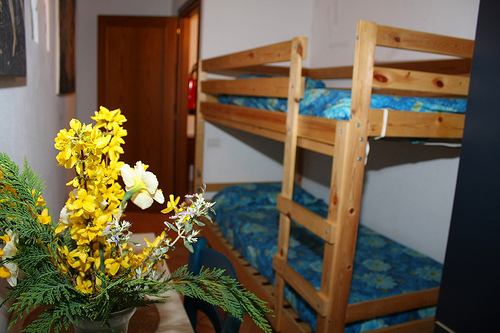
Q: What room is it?
A: It is a bedroom.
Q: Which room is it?
A: It is a bedroom.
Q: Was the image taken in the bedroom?
A: Yes, it was taken in the bedroom.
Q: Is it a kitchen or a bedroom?
A: It is a bedroom.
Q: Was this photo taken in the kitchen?
A: No, the picture was taken in the bedroom.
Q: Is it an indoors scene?
A: Yes, it is indoors.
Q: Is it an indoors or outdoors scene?
A: It is indoors.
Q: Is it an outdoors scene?
A: No, it is indoors.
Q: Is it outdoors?
A: No, it is indoors.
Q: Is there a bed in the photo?
A: Yes, there is a bed.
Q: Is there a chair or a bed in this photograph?
A: Yes, there is a bed.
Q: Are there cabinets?
A: No, there are no cabinets.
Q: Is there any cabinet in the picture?
A: No, there are no cabinets.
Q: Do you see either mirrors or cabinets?
A: No, there are no cabinets or mirrors.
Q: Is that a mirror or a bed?
A: That is a bed.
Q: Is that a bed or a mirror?
A: That is a bed.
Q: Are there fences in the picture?
A: No, there are no fences.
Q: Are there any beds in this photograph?
A: Yes, there is a bed.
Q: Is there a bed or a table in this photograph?
A: Yes, there is a bed.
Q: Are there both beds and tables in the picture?
A: Yes, there are both a bed and a table.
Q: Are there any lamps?
A: No, there are no lamps.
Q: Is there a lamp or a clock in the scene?
A: No, there are no lamps or clocks.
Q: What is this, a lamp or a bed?
A: This is a bed.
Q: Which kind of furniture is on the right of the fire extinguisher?
A: The piece of furniture is a bed.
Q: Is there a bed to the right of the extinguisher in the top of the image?
A: Yes, there is a bed to the right of the fire extinguisher.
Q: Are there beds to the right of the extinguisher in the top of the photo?
A: Yes, there is a bed to the right of the fire extinguisher.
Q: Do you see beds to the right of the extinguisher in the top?
A: Yes, there is a bed to the right of the fire extinguisher.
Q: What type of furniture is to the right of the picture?
A: The piece of furniture is a bed.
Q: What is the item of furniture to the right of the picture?
A: The piece of furniture is a bed.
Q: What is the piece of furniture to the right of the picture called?
A: The piece of furniture is a bed.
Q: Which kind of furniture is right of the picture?
A: The piece of furniture is a bed.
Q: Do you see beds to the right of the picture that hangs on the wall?
A: Yes, there is a bed to the right of the picture.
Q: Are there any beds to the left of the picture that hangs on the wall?
A: No, the bed is to the right of the picture.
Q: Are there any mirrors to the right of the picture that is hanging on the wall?
A: No, there is a bed to the right of the picture.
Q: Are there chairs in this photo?
A: Yes, there is a chair.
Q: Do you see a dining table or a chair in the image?
A: Yes, there is a chair.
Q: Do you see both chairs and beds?
A: Yes, there are both a chair and a bed.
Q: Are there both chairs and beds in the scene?
A: Yes, there are both a chair and a bed.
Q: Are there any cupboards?
A: No, there are no cupboards.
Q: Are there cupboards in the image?
A: No, there are no cupboards.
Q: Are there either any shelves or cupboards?
A: No, there are no cupboards or shelves.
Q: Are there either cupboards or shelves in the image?
A: No, there are no cupboards or shelves.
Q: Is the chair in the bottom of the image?
A: Yes, the chair is in the bottom of the image.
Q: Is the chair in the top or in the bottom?
A: The chair is in the bottom of the image.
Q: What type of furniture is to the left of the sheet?
A: The piece of furniture is a chair.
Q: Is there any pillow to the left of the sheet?
A: No, there is a chair to the left of the sheet.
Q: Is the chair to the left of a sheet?
A: Yes, the chair is to the left of a sheet.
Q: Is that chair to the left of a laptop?
A: No, the chair is to the left of a sheet.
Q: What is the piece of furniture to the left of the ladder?
A: The piece of furniture is a chair.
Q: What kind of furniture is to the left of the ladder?
A: The piece of furniture is a chair.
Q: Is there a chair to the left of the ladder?
A: Yes, there is a chair to the left of the ladder.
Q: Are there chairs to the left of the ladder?
A: Yes, there is a chair to the left of the ladder.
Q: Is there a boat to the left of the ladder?
A: No, there is a chair to the left of the ladder.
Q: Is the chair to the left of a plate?
A: No, the chair is to the left of the ladder.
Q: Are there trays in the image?
A: No, there are no trays.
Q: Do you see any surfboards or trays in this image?
A: No, there are no trays or surfboards.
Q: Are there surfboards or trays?
A: No, there are no trays or surfboards.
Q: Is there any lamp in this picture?
A: No, there are no lamps.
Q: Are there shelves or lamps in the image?
A: No, there are no lamps or shelves.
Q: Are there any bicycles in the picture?
A: No, there are no bicycles.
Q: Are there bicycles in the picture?
A: No, there are no bicycles.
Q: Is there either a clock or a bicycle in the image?
A: No, there are no bicycles or clocks.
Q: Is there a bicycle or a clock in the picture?
A: No, there are no bicycles or clocks.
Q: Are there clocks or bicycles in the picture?
A: No, there are no bicycles or clocks.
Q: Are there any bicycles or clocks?
A: No, there are no bicycles or clocks.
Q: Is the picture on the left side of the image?
A: Yes, the picture is on the left of the image.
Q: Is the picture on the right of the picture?
A: No, the picture is on the left of the image.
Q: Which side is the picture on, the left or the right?
A: The picture is on the left of the image.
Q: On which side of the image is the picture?
A: The picture is on the left of the image.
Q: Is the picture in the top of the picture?
A: Yes, the picture is in the top of the image.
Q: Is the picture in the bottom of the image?
A: No, the picture is in the top of the image.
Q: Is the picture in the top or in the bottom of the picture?
A: The picture is in the top of the image.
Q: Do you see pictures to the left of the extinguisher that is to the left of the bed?
A: Yes, there is a picture to the left of the extinguisher.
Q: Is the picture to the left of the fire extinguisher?
A: Yes, the picture is to the left of the fire extinguisher.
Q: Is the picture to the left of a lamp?
A: No, the picture is to the left of the fire extinguisher.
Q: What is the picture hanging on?
A: The picture is hanging on the wall.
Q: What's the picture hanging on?
A: The picture is hanging on the wall.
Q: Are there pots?
A: No, there are no pots.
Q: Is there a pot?
A: No, there are no pots.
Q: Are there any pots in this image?
A: No, there are no pots.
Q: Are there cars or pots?
A: No, there are no pots or cars.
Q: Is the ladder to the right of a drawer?
A: No, the ladder is to the right of the chair.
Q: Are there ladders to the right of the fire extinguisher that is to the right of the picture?
A: Yes, there is a ladder to the right of the extinguisher.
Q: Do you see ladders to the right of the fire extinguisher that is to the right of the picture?
A: Yes, there is a ladder to the right of the extinguisher.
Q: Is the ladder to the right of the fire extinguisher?
A: Yes, the ladder is to the right of the fire extinguisher.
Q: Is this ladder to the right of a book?
A: No, the ladder is to the right of the fire extinguisher.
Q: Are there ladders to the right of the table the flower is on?
A: Yes, there is a ladder to the right of the table.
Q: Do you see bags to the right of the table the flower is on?
A: No, there is a ladder to the right of the table.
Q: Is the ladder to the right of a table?
A: Yes, the ladder is to the right of a table.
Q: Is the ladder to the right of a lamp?
A: No, the ladder is to the right of a table.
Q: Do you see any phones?
A: No, there are no phones.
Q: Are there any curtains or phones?
A: No, there are no phones or curtains.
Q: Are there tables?
A: Yes, there is a table.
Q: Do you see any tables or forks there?
A: Yes, there is a table.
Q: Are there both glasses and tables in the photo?
A: No, there is a table but no glasses.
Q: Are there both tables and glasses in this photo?
A: No, there is a table but no glasses.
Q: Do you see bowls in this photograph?
A: No, there are no bowls.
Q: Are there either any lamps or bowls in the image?
A: No, there are no bowls or lamps.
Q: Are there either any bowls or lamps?
A: No, there are no bowls or lamps.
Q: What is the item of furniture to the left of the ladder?
A: The piece of furniture is a table.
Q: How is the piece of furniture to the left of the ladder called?
A: The piece of furniture is a table.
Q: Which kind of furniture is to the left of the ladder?
A: The piece of furniture is a table.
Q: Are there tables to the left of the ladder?
A: Yes, there is a table to the left of the ladder.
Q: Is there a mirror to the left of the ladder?
A: No, there is a table to the left of the ladder.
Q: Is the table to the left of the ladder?
A: Yes, the table is to the left of the ladder.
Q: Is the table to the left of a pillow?
A: No, the table is to the left of the ladder.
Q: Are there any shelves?
A: No, there are no shelves.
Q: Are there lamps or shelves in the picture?
A: No, there are no shelves or lamps.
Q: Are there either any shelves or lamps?
A: No, there are no shelves or lamps.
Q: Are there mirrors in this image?
A: No, there are no mirrors.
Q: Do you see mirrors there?
A: No, there are no mirrors.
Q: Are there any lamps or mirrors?
A: No, there are no mirrors or lamps.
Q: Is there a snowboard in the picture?
A: No, there are no snowboards.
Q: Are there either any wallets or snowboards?
A: No, there are no snowboards or wallets.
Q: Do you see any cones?
A: No, there are no cones.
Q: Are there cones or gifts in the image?
A: No, there are no cones or gifts.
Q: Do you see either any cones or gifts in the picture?
A: No, there are no cones or gifts.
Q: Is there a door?
A: Yes, there are doors.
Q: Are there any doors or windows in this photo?
A: Yes, there are doors.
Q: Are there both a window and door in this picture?
A: No, there are doors but no windows.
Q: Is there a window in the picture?
A: No, there are no windows.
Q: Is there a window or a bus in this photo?
A: No, there are no windows or buses.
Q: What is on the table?
A: The flower is on the table.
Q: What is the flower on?
A: The flower is on the table.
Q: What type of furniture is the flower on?
A: The flower is on the table.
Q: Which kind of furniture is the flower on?
A: The flower is on the table.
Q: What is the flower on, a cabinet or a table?
A: The flower is on a table.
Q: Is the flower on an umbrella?
A: No, the flower is on a table.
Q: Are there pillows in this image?
A: No, there are no pillows.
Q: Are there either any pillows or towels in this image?
A: No, there are no pillows or towels.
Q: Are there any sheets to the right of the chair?
A: Yes, there is a sheet to the right of the chair.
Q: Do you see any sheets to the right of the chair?
A: Yes, there is a sheet to the right of the chair.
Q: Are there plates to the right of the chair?
A: No, there is a sheet to the right of the chair.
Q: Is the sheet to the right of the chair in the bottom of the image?
A: Yes, the sheet is to the right of the chair.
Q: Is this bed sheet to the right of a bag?
A: No, the bed sheet is to the right of the chair.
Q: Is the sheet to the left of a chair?
A: No, the sheet is to the right of a chair.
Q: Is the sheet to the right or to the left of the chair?
A: The sheet is to the right of the chair.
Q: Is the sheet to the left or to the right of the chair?
A: The sheet is to the right of the chair.